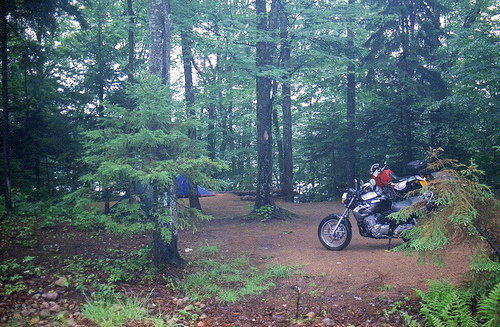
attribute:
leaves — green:
[190, 158, 231, 176]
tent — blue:
[150, 164, 210, 211]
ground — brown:
[1, 191, 498, 323]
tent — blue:
[110, 171, 215, 208]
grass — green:
[69, 234, 320, 325]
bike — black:
[318, 154, 443, 249]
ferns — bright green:
[404, 262, 497, 319]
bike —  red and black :
[356, 152, 433, 197]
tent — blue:
[133, 162, 223, 207]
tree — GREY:
[252, 4, 274, 209]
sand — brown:
[0, 190, 498, 324]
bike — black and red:
[321, 165, 453, 284]